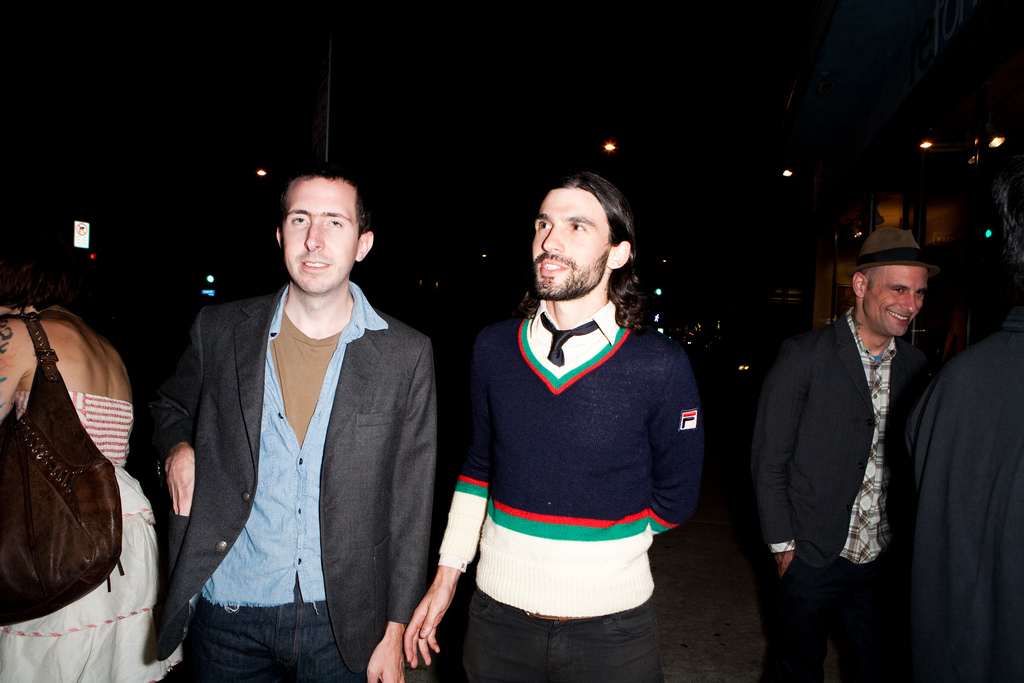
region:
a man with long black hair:
[506, 170, 649, 338]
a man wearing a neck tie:
[520, 186, 634, 365]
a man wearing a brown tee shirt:
[210, 170, 436, 452]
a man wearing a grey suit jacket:
[181, 170, 438, 658]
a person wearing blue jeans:
[185, 595, 364, 678]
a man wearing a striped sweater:
[453, 190, 711, 620]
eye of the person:
[282, 215, 312, 232]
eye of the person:
[542, 222, 553, 224]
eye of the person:
[588, 227, 601, 238]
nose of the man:
[544, 233, 573, 246]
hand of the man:
[381, 590, 432, 654]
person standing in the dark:
[2, 240, 171, 678]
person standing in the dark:
[373, 158, 718, 672]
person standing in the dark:
[747, 220, 934, 672]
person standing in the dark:
[364, 154, 709, 677]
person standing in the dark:
[160, 151, 440, 679]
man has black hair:
[523, 171, 625, 232]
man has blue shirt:
[473, 317, 692, 565]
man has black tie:
[512, 300, 629, 405]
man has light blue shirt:
[169, 230, 446, 677]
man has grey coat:
[0, 300, 444, 519]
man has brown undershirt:
[239, 300, 341, 419]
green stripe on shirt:
[453, 464, 657, 528]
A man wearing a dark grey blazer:
[140, 159, 450, 676]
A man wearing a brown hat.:
[757, 213, 945, 673]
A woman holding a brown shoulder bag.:
[1, 213, 208, 679]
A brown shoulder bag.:
[0, 289, 108, 643]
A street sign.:
[69, 213, 95, 252]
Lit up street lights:
[248, 130, 1020, 184]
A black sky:
[9, 4, 1015, 324]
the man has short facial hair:
[405, 174, 700, 677]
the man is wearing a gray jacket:
[150, 162, 442, 674]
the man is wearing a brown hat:
[751, 222, 938, 679]